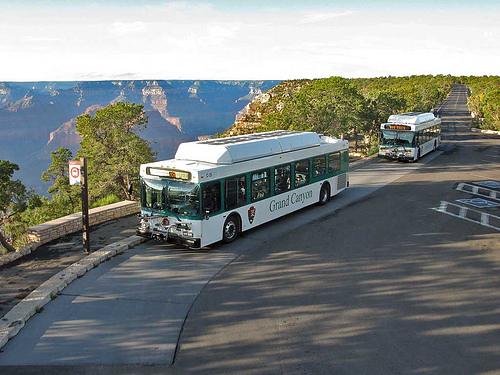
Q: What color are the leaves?
A: Green.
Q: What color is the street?
A: Gray.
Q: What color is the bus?
A: White.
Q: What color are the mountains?
A: Brown.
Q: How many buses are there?
A: 2.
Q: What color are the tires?
A: Black.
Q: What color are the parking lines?
A: White.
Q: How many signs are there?
A: One.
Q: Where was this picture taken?
A: The Grand Canyon.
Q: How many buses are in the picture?
A: Two.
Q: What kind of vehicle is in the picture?
A: Buses.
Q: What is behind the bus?
A: The Grand Canyon.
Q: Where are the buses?
A: In a parking lot.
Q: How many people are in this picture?
A: Zero.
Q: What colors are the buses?
A: Green and white.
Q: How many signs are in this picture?
A: One.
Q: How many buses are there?
A: Two.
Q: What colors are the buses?
A: White and green.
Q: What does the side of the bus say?
A: Grand Canyon.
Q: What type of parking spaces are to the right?
A: Handicap.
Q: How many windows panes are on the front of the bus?
A: Two.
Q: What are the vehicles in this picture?
A: Buses.